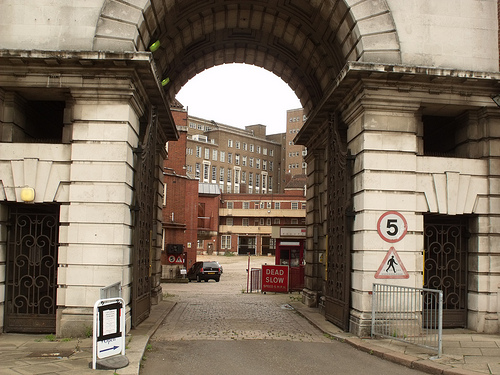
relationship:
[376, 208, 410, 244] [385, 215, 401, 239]
sign has 5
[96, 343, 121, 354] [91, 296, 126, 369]
arrow on sign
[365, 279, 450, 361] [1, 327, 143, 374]
barrier on sidewalk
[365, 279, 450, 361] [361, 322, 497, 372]
barrier on sidewalk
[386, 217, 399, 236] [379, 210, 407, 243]
5 on sign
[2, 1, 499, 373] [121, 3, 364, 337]
building has arch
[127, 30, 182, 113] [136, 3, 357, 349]
lights near top of arch